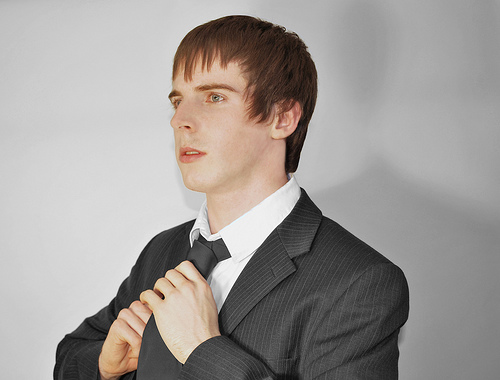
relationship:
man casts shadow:
[49, 17, 409, 377] [278, 2, 498, 377]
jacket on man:
[31, 198, 406, 378] [49, 17, 409, 377]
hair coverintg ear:
[176, 23, 313, 133] [260, 94, 308, 156]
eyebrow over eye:
[198, 85, 247, 97] [205, 97, 223, 104]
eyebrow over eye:
[198, 85, 247, 97] [174, 101, 184, 111]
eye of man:
[170, 96, 185, 108] [49, 17, 409, 377]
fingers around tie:
[116, 250, 198, 357] [124, 232, 239, 377]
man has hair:
[49, 17, 409, 377] [170, 14, 317, 174]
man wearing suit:
[49, 17, 409, 377] [52, 174, 410, 378]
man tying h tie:
[49, 17, 409, 377] [187, 234, 219, 272]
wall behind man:
[17, 14, 498, 371] [49, 17, 409, 377]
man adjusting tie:
[49, 17, 409, 377] [136, 226, 233, 377]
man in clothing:
[49, 17, 409, 377] [52, 175, 410, 378]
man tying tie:
[49, 17, 409, 377] [136, 226, 233, 377]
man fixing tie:
[49, 17, 409, 377] [136, 226, 233, 377]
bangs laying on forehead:
[165, 29, 246, 70] [171, 63, 253, 90]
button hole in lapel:
[262, 265, 285, 277] [216, 188, 322, 338]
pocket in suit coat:
[263, 358, 302, 377] [54, 185, 409, 378]